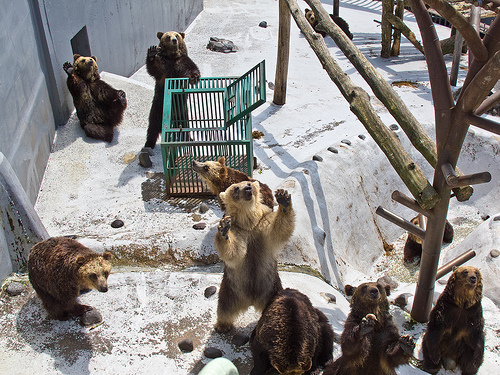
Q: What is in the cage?
A: Nothing.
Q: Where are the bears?
A: In the zoo.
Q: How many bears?
A: 10.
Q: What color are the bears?
A: Brown.